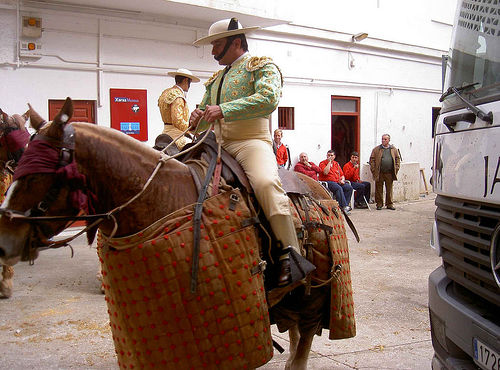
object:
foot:
[274, 247, 313, 287]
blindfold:
[11, 139, 101, 210]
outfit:
[193, 53, 301, 256]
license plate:
[473, 340, 500, 369]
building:
[0, 0, 452, 230]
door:
[330, 94, 361, 185]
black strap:
[212, 16, 243, 61]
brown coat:
[367, 141, 404, 181]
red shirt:
[342, 160, 362, 182]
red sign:
[105, 85, 152, 142]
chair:
[314, 171, 355, 218]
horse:
[0, 96, 342, 368]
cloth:
[96, 187, 275, 369]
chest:
[94, 174, 239, 320]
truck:
[426, 0, 500, 369]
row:
[269, 124, 415, 215]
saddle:
[180, 129, 314, 202]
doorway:
[327, 96, 364, 173]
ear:
[46, 95, 79, 140]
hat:
[191, 16, 264, 48]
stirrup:
[266, 245, 318, 296]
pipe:
[94, 19, 105, 110]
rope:
[31, 110, 215, 255]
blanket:
[93, 185, 274, 369]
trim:
[225, 15, 243, 34]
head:
[209, 20, 248, 66]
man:
[369, 132, 403, 212]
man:
[186, 16, 311, 287]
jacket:
[192, 52, 287, 146]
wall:
[0, 0, 461, 207]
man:
[155, 66, 203, 153]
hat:
[167, 67, 204, 84]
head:
[0, 96, 87, 270]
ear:
[26, 101, 46, 130]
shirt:
[381, 144, 392, 174]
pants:
[372, 169, 399, 208]